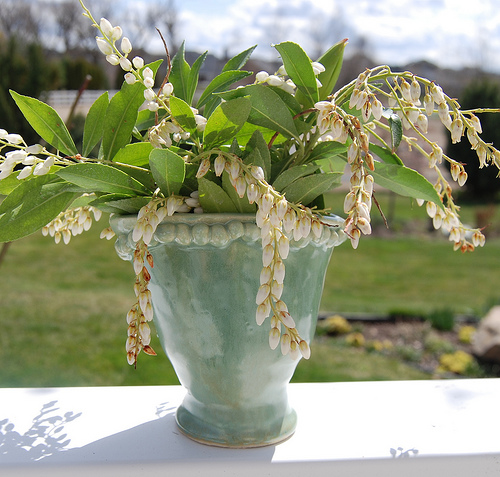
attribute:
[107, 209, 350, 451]
vase — decorative, blue, white, mint, green, clay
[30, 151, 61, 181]
flower — dead, white, wilted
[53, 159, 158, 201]
leaf — green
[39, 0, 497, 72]
sky — cloudy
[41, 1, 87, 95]
tree — leafless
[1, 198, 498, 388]
yard — green